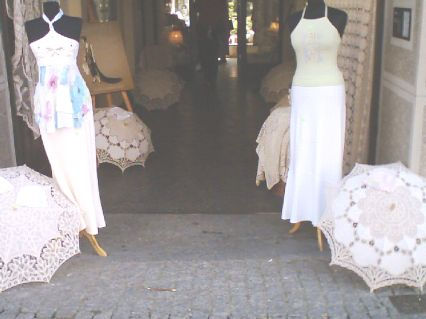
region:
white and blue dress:
[9, 21, 110, 139]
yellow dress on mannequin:
[273, 23, 331, 98]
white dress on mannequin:
[270, 89, 346, 226]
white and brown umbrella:
[301, 174, 423, 310]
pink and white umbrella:
[0, 156, 83, 298]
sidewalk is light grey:
[150, 234, 270, 318]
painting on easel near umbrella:
[76, 33, 136, 112]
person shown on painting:
[81, 41, 128, 97]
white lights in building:
[154, 9, 286, 77]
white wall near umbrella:
[352, 60, 423, 162]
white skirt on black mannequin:
[271, 73, 357, 227]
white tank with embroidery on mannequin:
[291, 5, 343, 86]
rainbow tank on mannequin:
[28, 7, 93, 132]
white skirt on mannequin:
[35, 94, 108, 243]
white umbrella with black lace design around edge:
[3, 161, 82, 292]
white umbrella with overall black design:
[314, 161, 424, 297]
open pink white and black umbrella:
[94, 100, 163, 172]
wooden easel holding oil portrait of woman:
[75, 0, 141, 136]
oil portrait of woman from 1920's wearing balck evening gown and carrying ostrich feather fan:
[72, 14, 136, 97]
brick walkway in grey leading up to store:
[10, 206, 401, 317]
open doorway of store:
[3, 3, 397, 227]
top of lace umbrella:
[319, 161, 423, 290]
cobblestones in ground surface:
[0, 255, 415, 317]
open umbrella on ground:
[0, 165, 85, 288]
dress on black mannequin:
[282, 1, 347, 226]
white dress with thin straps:
[287, 5, 346, 222]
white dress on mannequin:
[24, 13, 104, 238]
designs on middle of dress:
[34, 63, 91, 132]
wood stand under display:
[74, 231, 108, 257]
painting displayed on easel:
[79, 13, 135, 114]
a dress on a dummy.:
[16, 7, 111, 237]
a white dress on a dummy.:
[274, 3, 349, 229]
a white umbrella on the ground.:
[0, 160, 87, 296]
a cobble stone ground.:
[1, 255, 400, 315]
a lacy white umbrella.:
[308, 157, 424, 295]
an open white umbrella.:
[89, 105, 155, 167]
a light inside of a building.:
[170, 29, 184, 42]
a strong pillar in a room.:
[235, 0, 250, 76]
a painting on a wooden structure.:
[72, 21, 140, 109]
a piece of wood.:
[77, 228, 113, 263]